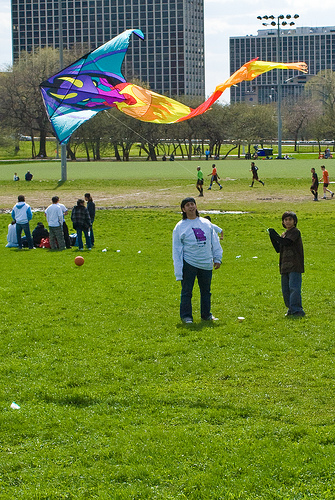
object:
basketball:
[73, 255, 83, 266]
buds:
[222, 106, 276, 155]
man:
[206, 163, 223, 191]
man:
[247, 163, 265, 188]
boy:
[266, 212, 305, 318]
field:
[0, 138, 335, 499]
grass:
[0, 195, 335, 499]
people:
[171, 195, 223, 324]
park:
[0, 132, 335, 497]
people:
[309, 166, 319, 202]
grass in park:
[0, 140, 335, 489]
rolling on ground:
[74, 254, 86, 269]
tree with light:
[301, 67, 335, 157]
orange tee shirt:
[210, 168, 218, 179]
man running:
[248, 158, 264, 191]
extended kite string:
[102, 109, 268, 230]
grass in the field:
[0, 197, 334, 499]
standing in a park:
[45, 194, 65, 251]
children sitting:
[4, 218, 17, 249]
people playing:
[179, 160, 334, 200]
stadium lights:
[288, 21, 296, 26]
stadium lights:
[269, 19, 277, 27]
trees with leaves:
[254, 110, 260, 114]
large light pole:
[275, 19, 283, 159]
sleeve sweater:
[267, 227, 305, 273]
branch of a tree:
[9, 116, 56, 136]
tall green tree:
[0, 45, 62, 158]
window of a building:
[154, 39, 160, 49]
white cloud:
[203, 0, 334, 104]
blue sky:
[204, 3, 334, 105]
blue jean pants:
[280, 270, 305, 315]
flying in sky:
[37, 27, 308, 146]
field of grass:
[0, 198, 335, 498]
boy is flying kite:
[40, 27, 310, 318]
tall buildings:
[10, 1, 205, 130]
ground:
[0, 136, 335, 498]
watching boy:
[267, 210, 305, 317]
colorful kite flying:
[37, 29, 308, 147]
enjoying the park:
[0, 27, 307, 323]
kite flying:
[41, 29, 309, 235]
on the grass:
[4, 189, 96, 253]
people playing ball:
[157, 154, 335, 209]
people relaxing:
[11, 193, 33, 250]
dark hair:
[181, 195, 199, 221]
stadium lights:
[292, 13, 300, 21]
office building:
[230, 27, 335, 141]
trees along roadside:
[273, 94, 319, 151]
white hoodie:
[171, 216, 224, 283]